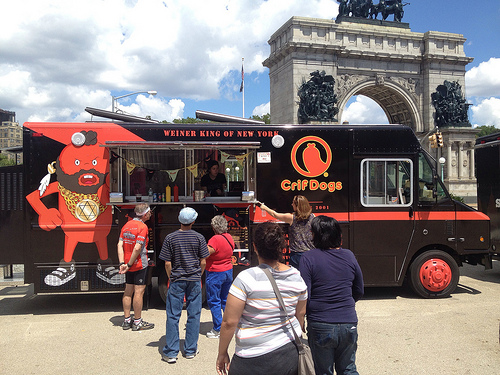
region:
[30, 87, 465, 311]
black and red hot dog truck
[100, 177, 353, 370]
people waiting in line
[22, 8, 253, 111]
large white clouds covering sky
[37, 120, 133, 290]
caricuture of Mr. T on truck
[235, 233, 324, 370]
purse around woman's chest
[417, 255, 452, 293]
hub caps painted red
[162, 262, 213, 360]
man wearing blue jeans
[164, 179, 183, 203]
mustard and ketchup bottles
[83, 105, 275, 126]
vents on the roof of the food truck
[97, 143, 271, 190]
flags hanging across ordering window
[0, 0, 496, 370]
Exterior, sunlit view, most likely taken before late fall, or winter.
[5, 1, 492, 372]
Summery, vacation-style scene.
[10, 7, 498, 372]
Shot, predominantly featuring, food truck, customers and monument.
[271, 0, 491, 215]
Ornate, concrete monument with statuary and archway.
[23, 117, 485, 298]
Large, mostly brown, food truck, with vendors at two windows.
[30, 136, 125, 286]
Mr. T-like logo, on truck, representing,"Weiner King,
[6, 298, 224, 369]
Cream-colored, cement surface with shadows on it.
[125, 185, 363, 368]
Group of people, in casual, summer clothes, awaiting their turn.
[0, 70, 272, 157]
Flag on pole, light post, and high-rise building, in distance.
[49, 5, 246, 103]
Heavy white clouds, in otherwise blue sky.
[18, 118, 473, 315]
side of parked food truck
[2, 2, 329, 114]
white clouds in sky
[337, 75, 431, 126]
arched opening in structure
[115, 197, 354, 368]
group of people facing truck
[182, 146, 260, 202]
open window on truck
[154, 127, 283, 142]
red words on truck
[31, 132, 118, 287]
cartoon left of windows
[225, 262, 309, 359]
striped shirt on woman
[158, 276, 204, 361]
blue jeans on man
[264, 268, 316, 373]
strap on gray handbag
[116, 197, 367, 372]
People waiting in line at food truck.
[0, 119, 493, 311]
Hot dog truck parked on pavement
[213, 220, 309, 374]
Woman wearing grey and white shirt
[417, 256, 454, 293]
Truck's orange hubcap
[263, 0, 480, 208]
Monumental archway behind truck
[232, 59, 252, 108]
Flag flying from pole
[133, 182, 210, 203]
Condiments on truck's counter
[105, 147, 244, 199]
Hot dog truck's ordering window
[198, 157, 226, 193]
Person in hot dog truck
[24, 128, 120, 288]
Drawing on side of food truck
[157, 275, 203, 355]
Blue jeans on person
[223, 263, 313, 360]
White striped shirt on person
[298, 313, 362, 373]
Dark jeans on person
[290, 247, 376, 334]
Purple shirt on person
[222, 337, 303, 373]
Gray pants on person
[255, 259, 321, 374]
gray bag person is carrying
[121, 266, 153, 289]
Black shorts on person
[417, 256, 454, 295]
Red rims on truck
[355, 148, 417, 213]
Side window on truck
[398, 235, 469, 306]
Front tire on truck